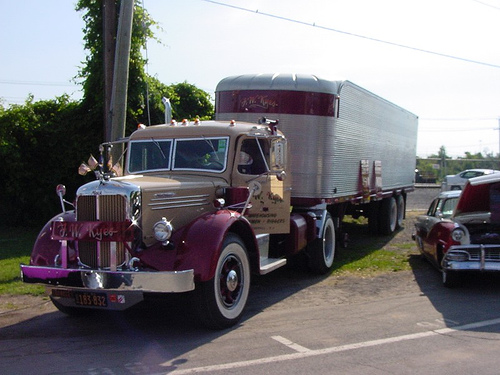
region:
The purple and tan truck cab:
[8, 97, 300, 340]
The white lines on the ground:
[147, 307, 499, 372]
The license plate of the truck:
[71, 290, 111, 311]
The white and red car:
[409, 170, 498, 294]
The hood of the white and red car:
[453, 167, 499, 223]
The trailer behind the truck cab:
[211, 65, 422, 206]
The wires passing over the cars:
[199, 2, 498, 71]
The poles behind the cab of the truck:
[99, 0, 140, 191]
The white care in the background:
[444, 162, 499, 190]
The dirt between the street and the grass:
[2, 265, 437, 342]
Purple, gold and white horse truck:
[19, 2, 421, 326]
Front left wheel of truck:
[213, 237, 255, 320]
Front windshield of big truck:
[122, 136, 230, 171]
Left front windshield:
[173, 136, 223, 171]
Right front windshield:
[126, 137, 171, 172]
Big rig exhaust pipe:
[104, 0, 132, 165]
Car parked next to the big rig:
[413, 189, 498, 289]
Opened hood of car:
[445, 171, 498, 236]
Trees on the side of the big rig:
[0, 0, 214, 257]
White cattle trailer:
[213, 73, 418, 203]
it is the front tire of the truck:
[198, 247, 256, 322]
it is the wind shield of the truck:
[129, 136, 226, 174]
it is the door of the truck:
[235, 132, 295, 224]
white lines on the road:
[268, 333, 316, 367]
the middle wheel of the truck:
[304, 210, 345, 269]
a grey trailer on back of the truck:
[232, 75, 434, 199]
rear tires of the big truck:
[367, 197, 412, 226]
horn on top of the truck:
[157, 93, 177, 125]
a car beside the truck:
[421, 185, 498, 280]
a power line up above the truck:
[277, 10, 360, 38]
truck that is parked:
[30, 64, 431, 346]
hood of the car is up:
[414, 165, 499, 310]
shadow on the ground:
[0, 311, 211, 371]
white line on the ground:
[201, 307, 491, 371]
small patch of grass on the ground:
[347, 243, 404, 277]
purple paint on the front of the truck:
[17, 211, 239, 301]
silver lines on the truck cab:
[151, 189, 221, 216]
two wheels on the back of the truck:
[378, 191, 411, 238]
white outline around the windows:
[125, 131, 235, 178]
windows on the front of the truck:
[130, 134, 225, 177]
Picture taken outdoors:
[7, 24, 497, 354]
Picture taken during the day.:
[21, 23, 438, 350]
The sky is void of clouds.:
[197, 20, 249, 44]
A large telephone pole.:
[97, 11, 134, 118]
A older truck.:
[15, 104, 313, 314]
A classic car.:
[422, 187, 480, 274]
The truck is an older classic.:
[20, 110, 324, 317]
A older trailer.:
[218, 63, 470, 205]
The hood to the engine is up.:
[455, 171, 489, 235]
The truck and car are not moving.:
[14, 191, 494, 312]